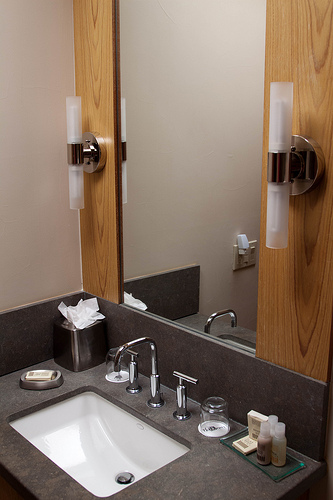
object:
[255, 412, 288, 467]
bottles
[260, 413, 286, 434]
caps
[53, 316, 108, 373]
tissue box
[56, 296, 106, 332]
paper towel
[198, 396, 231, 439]
glass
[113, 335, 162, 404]
faucet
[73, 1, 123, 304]
wood accent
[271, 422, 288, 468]
shampoo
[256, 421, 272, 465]
conditioner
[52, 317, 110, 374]
box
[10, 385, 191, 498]
sink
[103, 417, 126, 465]
porcelain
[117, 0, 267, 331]
wall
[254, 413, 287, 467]
toiletries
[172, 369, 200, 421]
fixture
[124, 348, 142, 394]
fixture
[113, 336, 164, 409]
fixture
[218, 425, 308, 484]
tray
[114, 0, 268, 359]
mirror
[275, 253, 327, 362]
wood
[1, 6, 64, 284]
wall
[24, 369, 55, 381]
soap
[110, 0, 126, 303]
frame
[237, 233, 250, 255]
light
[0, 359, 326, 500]
countertop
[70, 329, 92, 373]
reflection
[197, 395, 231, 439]
bottle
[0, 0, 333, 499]
photo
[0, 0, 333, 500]
bathroom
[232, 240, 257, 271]
socket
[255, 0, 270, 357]
frame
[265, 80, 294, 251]
lamp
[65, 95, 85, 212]
lamp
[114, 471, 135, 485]
drain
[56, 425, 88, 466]
reflection